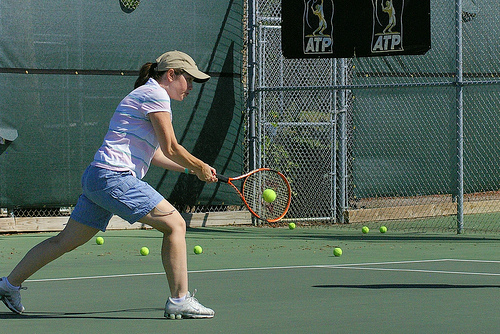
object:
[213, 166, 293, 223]
tennis racket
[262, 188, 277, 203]
tennis ball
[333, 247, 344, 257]
tennis ball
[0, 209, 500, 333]
tennis court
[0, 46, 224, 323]
woman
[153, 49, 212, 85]
baseball hat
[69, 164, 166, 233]
shorts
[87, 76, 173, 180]
shirt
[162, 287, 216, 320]
shoe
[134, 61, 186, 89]
hair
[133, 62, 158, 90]
ponytail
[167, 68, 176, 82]
ear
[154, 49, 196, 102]
head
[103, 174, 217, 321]
leg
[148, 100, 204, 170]
arm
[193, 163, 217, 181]
hand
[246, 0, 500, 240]
fence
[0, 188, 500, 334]
ground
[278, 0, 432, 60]
banner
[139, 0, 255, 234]
shadow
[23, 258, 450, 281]
line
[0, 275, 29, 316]
shoe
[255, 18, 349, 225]
gate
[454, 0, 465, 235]
pole